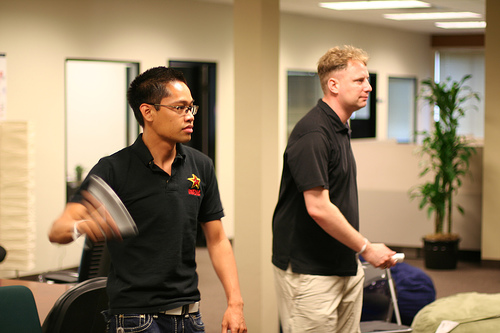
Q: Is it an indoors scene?
A: Yes, it is indoors.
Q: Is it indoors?
A: Yes, it is indoors.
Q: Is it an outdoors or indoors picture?
A: It is indoors.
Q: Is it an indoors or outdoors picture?
A: It is indoors.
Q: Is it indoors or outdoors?
A: It is indoors.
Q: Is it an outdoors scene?
A: No, it is indoors.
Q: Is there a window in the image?
A: Yes, there is a window.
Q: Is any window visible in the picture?
A: Yes, there is a window.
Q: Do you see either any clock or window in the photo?
A: Yes, there is a window.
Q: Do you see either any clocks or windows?
A: Yes, there is a window.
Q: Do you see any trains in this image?
A: No, there are no trains.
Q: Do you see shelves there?
A: No, there are no shelves.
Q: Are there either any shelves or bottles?
A: No, there are no shelves or bottles.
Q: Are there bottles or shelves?
A: No, there are no shelves or bottles.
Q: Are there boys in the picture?
A: No, there are no boys.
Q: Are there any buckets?
A: No, there are no buckets.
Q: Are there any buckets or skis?
A: No, there are no buckets or skis.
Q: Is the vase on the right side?
A: Yes, the vase is on the right of the image.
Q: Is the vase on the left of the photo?
A: No, the vase is on the right of the image.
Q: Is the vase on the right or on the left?
A: The vase is on the right of the image.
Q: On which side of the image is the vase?
A: The vase is on the right of the image.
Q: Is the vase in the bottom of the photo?
A: Yes, the vase is in the bottom of the image.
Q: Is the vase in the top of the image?
A: No, the vase is in the bottom of the image.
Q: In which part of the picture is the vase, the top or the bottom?
A: The vase is in the bottom of the image.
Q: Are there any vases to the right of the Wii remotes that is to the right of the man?
A: Yes, there is a vase to the right of the Wii controller.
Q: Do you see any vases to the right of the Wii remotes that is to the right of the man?
A: Yes, there is a vase to the right of the Wii controller.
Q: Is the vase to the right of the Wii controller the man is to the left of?
A: Yes, the vase is to the right of the Wii remotes.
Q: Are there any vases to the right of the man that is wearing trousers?
A: Yes, there is a vase to the right of the man.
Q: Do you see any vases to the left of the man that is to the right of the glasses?
A: No, the vase is to the right of the man.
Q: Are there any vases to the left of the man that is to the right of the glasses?
A: No, the vase is to the right of the man.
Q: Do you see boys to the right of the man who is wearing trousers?
A: No, there is a vase to the right of the man.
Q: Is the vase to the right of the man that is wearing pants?
A: Yes, the vase is to the right of the man.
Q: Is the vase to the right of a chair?
A: No, the vase is to the right of the man.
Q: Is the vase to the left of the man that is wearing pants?
A: No, the vase is to the right of the man.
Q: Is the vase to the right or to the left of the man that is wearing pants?
A: The vase is to the right of the man.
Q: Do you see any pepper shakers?
A: No, there are no pepper shakers.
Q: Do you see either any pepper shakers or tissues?
A: No, there are no pepper shakers or tissues.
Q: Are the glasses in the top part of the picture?
A: Yes, the glasses are in the top of the image.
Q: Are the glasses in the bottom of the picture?
A: No, the glasses are in the top of the image.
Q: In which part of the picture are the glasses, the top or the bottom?
A: The glasses are in the top of the image.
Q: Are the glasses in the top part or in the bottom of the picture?
A: The glasses are in the top of the image.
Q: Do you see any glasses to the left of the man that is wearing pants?
A: Yes, there are glasses to the left of the man.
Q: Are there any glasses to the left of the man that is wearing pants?
A: Yes, there are glasses to the left of the man.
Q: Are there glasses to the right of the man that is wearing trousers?
A: No, the glasses are to the left of the man.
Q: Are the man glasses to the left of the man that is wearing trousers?
A: Yes, the glasses are to the left of the man.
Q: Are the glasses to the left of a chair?
A: No, the glasses are to the left of the man.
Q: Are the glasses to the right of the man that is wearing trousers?
A: No, the glasses are to the left of the man.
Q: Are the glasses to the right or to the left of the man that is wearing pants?
A: The glasses are to the left of the man.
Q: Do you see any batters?
A: No, there are no batters.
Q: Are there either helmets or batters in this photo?
A: No, there are no batters or helmets.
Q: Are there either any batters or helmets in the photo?
A: No, there are no batters or helmets.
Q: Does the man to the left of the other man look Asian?
A: Yes, the man is asian.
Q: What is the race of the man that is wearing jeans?
A: The man is asian.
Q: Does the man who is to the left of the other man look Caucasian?
A: No, the man is asian.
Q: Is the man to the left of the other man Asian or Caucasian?
A: The man is asian.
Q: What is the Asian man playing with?
A: The man is playing with a Wii controller.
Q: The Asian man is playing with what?
A: The man is playing with a Wii controller.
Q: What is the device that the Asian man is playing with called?
A: The device is a Wii controller.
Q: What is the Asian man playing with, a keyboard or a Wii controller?
A: The man is playing with a Wii controller.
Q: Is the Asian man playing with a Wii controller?
A: Yes, the man is playing with a Wii controller.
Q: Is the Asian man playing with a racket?
A: No, the man is playing with a Wii controller.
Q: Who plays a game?
A: The man plays a game.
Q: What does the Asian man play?
A: The man plays a game.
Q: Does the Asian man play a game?
A: Yes, the man plays a game.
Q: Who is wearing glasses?
A: The man is wearing glasses.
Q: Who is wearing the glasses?
A: The man is wearing glasses.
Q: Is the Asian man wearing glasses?
A: Yes, the man is wearing glasses.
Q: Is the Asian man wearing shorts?
A: No, the man is wearing glasses.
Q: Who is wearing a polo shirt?
A: The man is wearing a polo shirt.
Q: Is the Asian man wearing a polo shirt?
A: Yes, the man is wearing a polo shirt.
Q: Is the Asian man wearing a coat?
A: No, the man is wearing a polo shirt.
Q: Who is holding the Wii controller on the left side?
A: The man is holding the Wii remotes.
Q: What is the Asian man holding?
A: The man is holding the Wii remotes.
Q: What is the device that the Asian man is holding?
A: The device is a Wii controller.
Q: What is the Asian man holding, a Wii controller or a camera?
A: The man is holding a Wii controller.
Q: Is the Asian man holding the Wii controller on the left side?
A: Yes, the man is holding the Wii controller.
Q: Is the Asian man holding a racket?
A: No, the man is holding the Wii controller.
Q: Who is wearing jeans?
A: The man is wearing jeans.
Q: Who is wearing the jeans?
A: The man is wearing jeans.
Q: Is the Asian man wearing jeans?
A: Yes, the man is wearing jeans.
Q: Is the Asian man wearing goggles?
A: No, the man is wearing jeans.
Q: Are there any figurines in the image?
A: No, there are no figurines.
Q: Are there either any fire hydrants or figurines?
A: No, there are no figurines or fire hydrants.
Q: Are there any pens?
A: No, there are no pens.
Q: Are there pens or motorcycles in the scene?
A: No, there are no pens or motorcycles.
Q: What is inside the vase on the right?
A: The plant is inside the vase.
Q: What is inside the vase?
A: The plant is inside the vase.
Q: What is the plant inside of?
A: The plant is inside the vase.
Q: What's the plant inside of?
A: The plant is inside the vase.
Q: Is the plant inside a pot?
A: No, the plant is inside the vase.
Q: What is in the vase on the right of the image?
A: The plant is in the vase.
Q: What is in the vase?
A: The plant is in the vase.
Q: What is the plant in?
A: The plant is in the vase.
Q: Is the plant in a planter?
A: No, the plant is in the vase.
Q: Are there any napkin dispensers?
A: No, there are no napkin dispensers.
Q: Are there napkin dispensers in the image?
A: No, there are no napkin dispensers.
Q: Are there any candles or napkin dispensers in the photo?
A: No, there are no napkin dispensers or candles.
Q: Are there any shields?
A: No, there are no shields.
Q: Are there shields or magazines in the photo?
A: No, there are no shields or magazines.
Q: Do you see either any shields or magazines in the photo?
A: No, there are no shields or magazines.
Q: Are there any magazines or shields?
A: No, there are no shields or magazines.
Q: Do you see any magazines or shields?
A: No, there are no shields or magazines.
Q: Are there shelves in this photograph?
A: No, there are no shelves.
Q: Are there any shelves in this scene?
A: No, there are no shelves.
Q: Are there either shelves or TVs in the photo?
A: No, there are no shelves or tvs.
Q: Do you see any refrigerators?
A: No, there are no refrigerators.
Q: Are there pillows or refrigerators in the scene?
A: No, there are no refrigerators or pillows.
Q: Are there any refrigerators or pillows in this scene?
A: No, there are no refrigerators or pillows.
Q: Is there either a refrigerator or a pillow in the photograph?
A: No, there are no refrigerators or pillows.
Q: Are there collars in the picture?
A: Yes, there is a collar.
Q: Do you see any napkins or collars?
A: Yes, there is a collar.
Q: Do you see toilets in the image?
A: No, there are no toilets.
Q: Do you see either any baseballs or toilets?
A: No, there are no toilets or baseballs.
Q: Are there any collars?
A: Yes, there is a collar.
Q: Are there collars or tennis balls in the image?
A: Yes, there is a collar.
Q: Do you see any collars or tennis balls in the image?
A: Yes, there is a collar.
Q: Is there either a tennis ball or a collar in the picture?
A: Yes, there is a collar.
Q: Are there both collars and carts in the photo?
A: No, there is a collar but no carts.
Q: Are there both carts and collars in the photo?
A: No, there is a collar but no carts.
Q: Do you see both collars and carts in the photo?
A: No, there is a collar but no carts.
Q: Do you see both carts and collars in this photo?
A: No, there is a collar but no carts.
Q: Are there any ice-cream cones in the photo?
A: No, there are no ice-cream cones.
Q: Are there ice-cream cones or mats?
A: No, there are no ice-cream cones or mats.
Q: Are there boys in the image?
A: No, there are no boys.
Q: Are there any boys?
A: No, there are no boys.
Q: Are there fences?
A: No, there are no fences.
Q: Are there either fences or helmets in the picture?
A: No, there are no fences or helmets.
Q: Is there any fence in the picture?
A: No, there are no fences.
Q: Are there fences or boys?
A: No, there are no fences or boys.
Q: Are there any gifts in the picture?
A: No, there are no gifts.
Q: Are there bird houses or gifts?
A: No, there are no gifts or bird houses.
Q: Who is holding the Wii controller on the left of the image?
A: The man is holding the Wii remotes.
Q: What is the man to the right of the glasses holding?
A: The man is holding the Wii controller.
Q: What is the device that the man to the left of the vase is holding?
A: The device is a Wii controller.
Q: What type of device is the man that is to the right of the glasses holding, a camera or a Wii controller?
A: The man is holding a Wii controller.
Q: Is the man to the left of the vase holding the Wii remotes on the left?
A: Yes, the man is holding the Wii controller.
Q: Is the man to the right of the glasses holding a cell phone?
A: No, the man is holding the Wii controller.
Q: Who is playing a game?
A: The man is playing a game.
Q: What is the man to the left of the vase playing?
A: The man is playing a game.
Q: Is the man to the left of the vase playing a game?
A: Yes, the man is playing a game.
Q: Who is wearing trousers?
A: The man is wearing trousers.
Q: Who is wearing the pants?
A: The man is wearing trousers.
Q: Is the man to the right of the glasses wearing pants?
A: Yes, the man is wearing pants.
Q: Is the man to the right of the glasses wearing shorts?
A: No, the man is wearing pants.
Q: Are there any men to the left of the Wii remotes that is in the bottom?
A: Yes, there is a man to the left of the Wii controller.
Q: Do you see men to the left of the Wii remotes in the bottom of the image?
A: Yes, there is a man to the left of the Wii controller.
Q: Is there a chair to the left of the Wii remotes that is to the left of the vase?
A: No, there is a man to the left of the Wii controller.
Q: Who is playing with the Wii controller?
A: The man is playing with the Wii controller.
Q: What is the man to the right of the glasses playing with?
A: The man is playing with a Wii remotes.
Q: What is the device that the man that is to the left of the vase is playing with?
A: The device is a Wii controller.